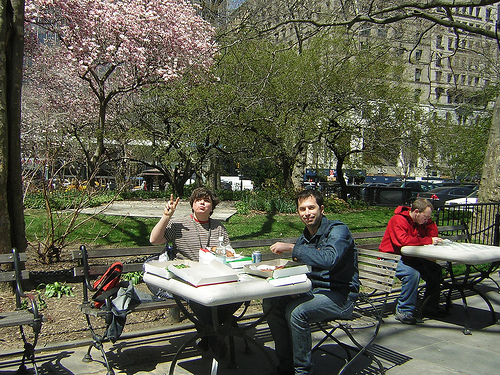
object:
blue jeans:
[262, 288, 354, 374]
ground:
[10, 199, 500, 374]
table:
[399, 239, 499, 335]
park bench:
[73, 225, 473, 374]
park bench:
[1, 249, 42, 375]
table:
[141, 257, 310, 374]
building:
[216, 12, 496, 197]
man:
[262, 189, 360, 373]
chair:
[296, 248, 402, 373]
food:
[249, 259, 299, 272]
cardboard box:
[144, 259, 239, 288]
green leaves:
[123, 267, 144, 286]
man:
[379, 199, 445, 324]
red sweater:
[376, 206, 438, 262]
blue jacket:
[290, 218, 361, 301]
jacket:
[103, 282, 166, 343]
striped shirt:
[160, 216, 231, 260]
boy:
[149, 188, 237, 359]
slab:
[59, 201, 240, 220]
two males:
[148, 188, 359, 375]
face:
[297, 194, 318, 225]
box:
[243, 257, 311, 278]